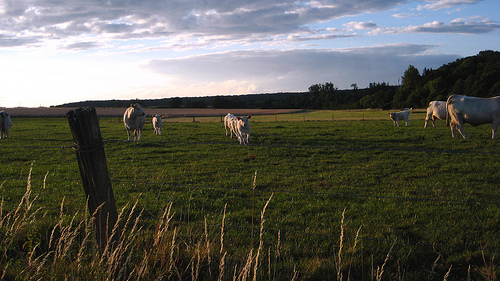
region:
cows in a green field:
[0, 95, 498, 141]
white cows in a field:
[0, 95, 497, 144]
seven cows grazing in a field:
[0, 94, 498, 144]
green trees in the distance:
[52, 49, 497, 107]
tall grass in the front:
[0, 162, 496, 279]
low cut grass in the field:
[1, 113, 498, 278]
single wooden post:
[67, 105, 124, 254]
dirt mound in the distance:
[1, 105, 298, 112]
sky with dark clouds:
[0, 0, 497, 105]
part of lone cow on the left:
[0, 110, 11, 135]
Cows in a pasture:
[376, 88, 498, 140]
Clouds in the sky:
[12, 6, 297, 92]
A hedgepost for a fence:
[50, 88, 135, 260]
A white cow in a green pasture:
[113, 98, 153, 147]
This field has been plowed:
[144, 101, 304, 117]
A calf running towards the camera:
[232, 113, 258, 152]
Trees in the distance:
[378, 66, 460, 102]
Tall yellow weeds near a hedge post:
[50, 177, 294, 277]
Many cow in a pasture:
[115, 77, 490, 179]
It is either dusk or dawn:
[19, 17, 365, 89]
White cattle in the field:
[114, 93, 498, 155]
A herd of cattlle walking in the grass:
[115, 93, 496, 175]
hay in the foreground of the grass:
[10, 177, 475, 278]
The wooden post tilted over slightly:
[56, 103, 121, 250]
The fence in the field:
[241, 112, 380, 124]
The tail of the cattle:
[445, 96, 451, 129]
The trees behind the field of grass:
[245, 76, 422, 108]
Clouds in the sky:
[0, 0, 382, 43]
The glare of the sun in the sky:
[1, 46, 91, 110]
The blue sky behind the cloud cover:
[311, 0, 498, 53]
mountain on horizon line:
[148, 81, 299, 103]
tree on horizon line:
[298, 76, 343, 102]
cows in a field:
[107, 94, 259, 156]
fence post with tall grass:
[59, 103, 121, 268]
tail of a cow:
[443, 92, 454, 129]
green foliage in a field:
[293, 133, 375, 180]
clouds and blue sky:
[177, 16, 321, 64]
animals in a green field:
[115, 93, 417, 180]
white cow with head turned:
[118, 99, 148, 144]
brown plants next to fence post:
[45, 106, 119, 271]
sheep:
[204, 108, 259, 141]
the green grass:
[292, 143, 424, 225]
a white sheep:
[116, 101, 161, 135]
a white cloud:
[145, 58, 260, 83]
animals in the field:
[385, 96, 495, 143]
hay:
[62, 218, 234, 279]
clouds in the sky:
[148, 50, 285, 89]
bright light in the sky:
[25, 60, 112, 90]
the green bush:
[433, 60, 483, 91]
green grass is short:
[258, 148, 417, 225]